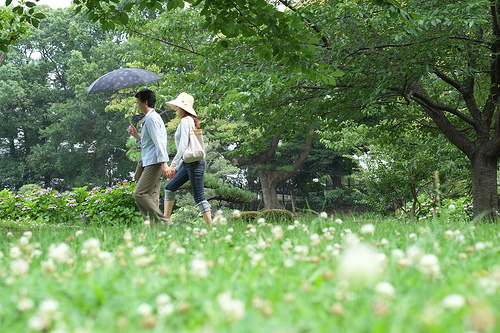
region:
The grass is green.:
[72, 242, 371, 326]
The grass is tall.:
[54, 239, 383, 330]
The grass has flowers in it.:
[75, 245, 346, 315]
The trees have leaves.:
[223, 8, 465, 127]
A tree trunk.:
[399, 70, 497, 232]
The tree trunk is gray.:
[421, 72, 498, 229]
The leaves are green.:
[249, 2, 429, 129]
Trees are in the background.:
[4, 17, 115, 183]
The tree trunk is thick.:
[393, 64, 498, 231]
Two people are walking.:
[78, 58, 217, 233]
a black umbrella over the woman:
[81, 58, 168, 99]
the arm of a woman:
[145, 112, 171, 161]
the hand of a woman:
[160, 160, 174, 177]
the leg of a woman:
[189, 162, 216, 228]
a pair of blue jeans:
[161, 153, 215, 218]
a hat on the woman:
[162, 87, 199, 119]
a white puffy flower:
[228, 202, 243, 220]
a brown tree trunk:
[463, 140, 499, 217]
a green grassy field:
[1, 203, 498, 331]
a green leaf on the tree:
[328, 66, 350, 80]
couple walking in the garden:
[80, 51, 218, 246]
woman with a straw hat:
[161, 77, 213, 221]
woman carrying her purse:
[142, 88, 212, 225]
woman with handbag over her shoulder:
[160, 87, 219, 234]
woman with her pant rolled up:
[158, 86, 213, 233]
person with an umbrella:
[82, 62, 172, 220]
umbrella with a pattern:
[75, 62, 162, 97]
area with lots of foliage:
[0, 0, 498, 192]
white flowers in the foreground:
[1, 220, 308, 320]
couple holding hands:
[83, 61, 222, 221]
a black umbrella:
[83, 59, 160, 96]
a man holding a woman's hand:
[126, 86, 171, 225]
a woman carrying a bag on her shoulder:
[166, 88, 215, 230]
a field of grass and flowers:
[5, 215, 494, 331]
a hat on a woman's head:
[166, 88, 203, 116]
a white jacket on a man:
[134, 109, 171, 166]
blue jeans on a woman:
[162, 152, 217, 212]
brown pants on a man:
[133, 163, 169, 222]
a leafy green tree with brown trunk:
[304, 14, 498, 225]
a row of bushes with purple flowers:
[1, 177, 133, 215]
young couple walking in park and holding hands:
[123, 86, 222, 228]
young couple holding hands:
[159, 163, 178, 182]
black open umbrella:
[79, 54, 158, 91]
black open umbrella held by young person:
[87, 64, 159, 89]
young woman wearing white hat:
[168, 83, 206, 110]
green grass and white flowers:
[24, 233, 128, 305]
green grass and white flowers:
[150, 241, 266, 304]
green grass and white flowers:
[250, 232, 366, 315]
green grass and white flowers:
[359, 229, 466, 311]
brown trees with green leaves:
[309, 24, 471, 192]